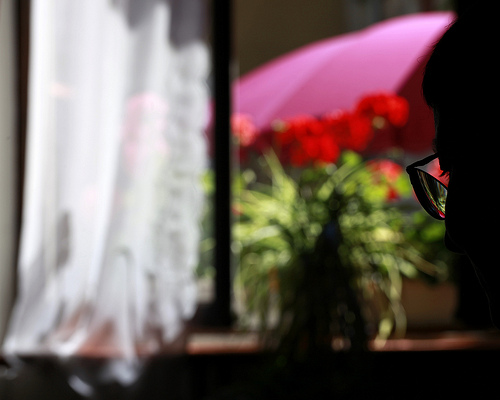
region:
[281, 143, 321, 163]
flower in the vase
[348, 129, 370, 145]
flower in the vase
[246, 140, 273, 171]
flower in the vase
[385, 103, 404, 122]
flower in the vase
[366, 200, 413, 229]
flower in the vase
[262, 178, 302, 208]
flower in the vase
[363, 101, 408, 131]
flower in the vase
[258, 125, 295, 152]
flower in the vase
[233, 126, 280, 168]
flower in the vase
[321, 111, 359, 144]
flower in the vase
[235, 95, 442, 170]
red flowers in a vase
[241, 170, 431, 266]
green leaves of the flowers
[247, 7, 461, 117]
purple umbrella in the background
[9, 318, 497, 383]
sill of a window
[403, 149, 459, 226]
eyeglass edge of a person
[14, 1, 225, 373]
white curtain on a window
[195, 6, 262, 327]
frame of a window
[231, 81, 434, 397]
flowers in a vase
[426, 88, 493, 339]
face of a man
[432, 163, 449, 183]
eyelash of a man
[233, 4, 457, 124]
a purple flower pedal.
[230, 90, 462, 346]
A bunch of red flowers.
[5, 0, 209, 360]
A white curtain in a window.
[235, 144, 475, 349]
A bunch of green flower stems.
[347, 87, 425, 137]
a flower on a stem.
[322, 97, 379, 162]
flowers on a stem.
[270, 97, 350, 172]
a red flower top.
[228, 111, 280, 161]
a long stem flower.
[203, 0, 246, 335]
a divider in a window.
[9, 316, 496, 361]
a brown window sill.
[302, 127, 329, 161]
flower in the vase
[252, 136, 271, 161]
flower in the vase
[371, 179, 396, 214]
flower in the vase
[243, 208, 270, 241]
flower in the vase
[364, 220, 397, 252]
flower in the vase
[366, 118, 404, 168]
flower in the vase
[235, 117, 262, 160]
flower in the vase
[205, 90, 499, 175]
a group of red flowers.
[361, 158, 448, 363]
A green flower stem.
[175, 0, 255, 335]
A window frame.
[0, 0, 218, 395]
A white curtain on a window.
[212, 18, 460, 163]
a pink open umbrella.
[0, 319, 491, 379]
a wooden window sill.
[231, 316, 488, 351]
light reflecting on a wood surface.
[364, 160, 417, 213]
a flower with a green stem.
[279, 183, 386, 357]
a large black object.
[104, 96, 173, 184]
red flowers behind a curtain.